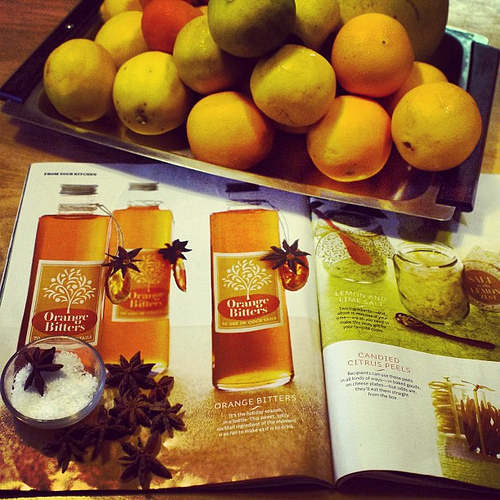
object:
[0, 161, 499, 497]
magazine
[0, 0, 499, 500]
table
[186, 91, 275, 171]
orange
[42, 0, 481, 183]
pile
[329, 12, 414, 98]
orange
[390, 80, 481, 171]
orange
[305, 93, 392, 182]
orange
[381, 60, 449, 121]
orange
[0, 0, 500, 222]
plate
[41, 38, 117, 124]
fruit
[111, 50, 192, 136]
lemon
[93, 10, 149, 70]
lemon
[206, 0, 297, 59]
lime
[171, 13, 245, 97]
lime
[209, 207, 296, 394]
alcohol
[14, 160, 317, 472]
image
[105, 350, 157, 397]
star anise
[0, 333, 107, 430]
bowl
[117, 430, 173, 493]
star anise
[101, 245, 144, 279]
star anise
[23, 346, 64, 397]
star anise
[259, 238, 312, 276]
star anise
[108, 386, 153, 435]
star anise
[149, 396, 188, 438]
star anise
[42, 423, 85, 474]
star anise